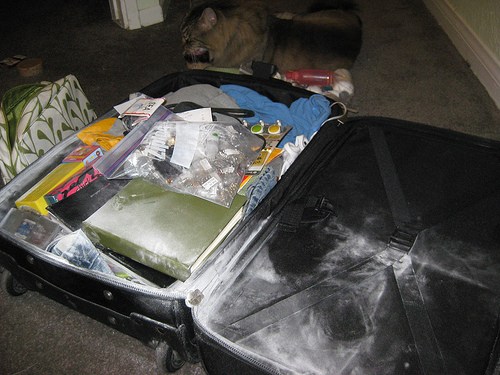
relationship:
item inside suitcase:
[89, 88, 161, 188] [1, 62, 498, 372]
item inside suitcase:
[79, 172, 247, 282] [1, 62, 498, 372]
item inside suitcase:
[79, 155, 251, 275] [1, 62, 498, 372]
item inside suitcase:
[267, 119, 284, 134] [19, 60, 480, 350]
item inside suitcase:
[281, 67, 340, 87] [1, 62, 498, 372]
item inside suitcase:
[267, 119, 284, 134] [1, 62, 498, 372]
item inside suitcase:
[45, 174, 164, 192] [1, 62, 498, 372]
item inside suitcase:
[230, 105, 288, 145] [1, 62, 498, 372]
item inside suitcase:
[3, 197, 67, 257] [1, 62, 498, 372]